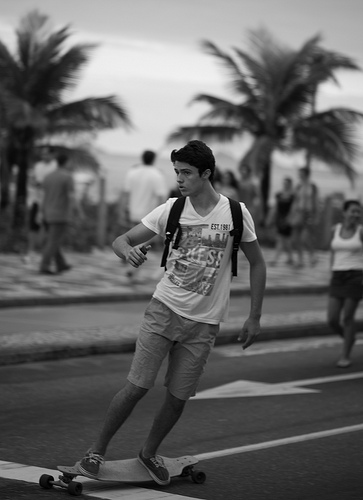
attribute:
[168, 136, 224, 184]
hair — short, black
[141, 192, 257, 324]
shirt — white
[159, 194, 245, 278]
straps — dark 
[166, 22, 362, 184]
palm tree — tall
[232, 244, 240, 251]
buckle — silver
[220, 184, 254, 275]
strap — black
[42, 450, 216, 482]
skateboard — long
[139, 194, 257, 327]
shortsleeve shirt — short sleeved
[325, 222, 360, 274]
tank top — white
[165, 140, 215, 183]
hair — short, black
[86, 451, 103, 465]
laces — white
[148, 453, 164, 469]
laces — white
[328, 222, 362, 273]
tank top — plain, white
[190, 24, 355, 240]
tree — large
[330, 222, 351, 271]
shirt — white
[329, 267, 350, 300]
skirt — short, black